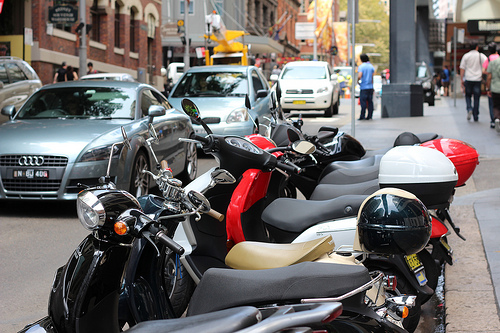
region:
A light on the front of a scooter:
[77, 191, 106, 227]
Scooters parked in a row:
[20, 122, 467, 329]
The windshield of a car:
[24, 83, 135, 123]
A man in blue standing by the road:
[352, 52, 376, 117]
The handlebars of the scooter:
[102, 175, 186, 256]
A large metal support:
[377, 39, 426, 113]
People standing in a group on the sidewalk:
[50, 59, 103, 86]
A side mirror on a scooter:
[295, 140, 315, 155]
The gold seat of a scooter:
[232, 232, 329, 268]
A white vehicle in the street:
[274, 57, 344, 114]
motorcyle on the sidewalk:
[55, 203, 372, 323]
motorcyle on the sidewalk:
[146, 185, 406, 257]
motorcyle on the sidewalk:
[205, 173, 412, 238]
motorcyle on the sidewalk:
[193, 161, 420, 214]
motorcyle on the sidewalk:
[238, 159, 443, 194]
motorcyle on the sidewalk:
[242, 120, 476, 185]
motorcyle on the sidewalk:
[83, 282, 365, 320]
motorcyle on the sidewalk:
[174, 225, 398, 290]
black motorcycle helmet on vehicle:
[351, 181, 433, 256]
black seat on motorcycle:
[188, 249, 360, 300]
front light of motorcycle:
[77, 186, 99, 221]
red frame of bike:
[238, 163, 265, 241]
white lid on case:
[395, 142, 453, 179]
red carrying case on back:
[438, 129, 469, 160]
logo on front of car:
[14, 143, 52, 165]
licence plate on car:
[14, 163, 58, 184]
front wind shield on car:
[2, 75, 130, 129]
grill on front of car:
[0, 156, 57, 174]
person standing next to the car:
[346, 42, 384, 122]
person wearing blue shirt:
[351, 62, 381, 98]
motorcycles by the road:
[124, 104, 418, 331]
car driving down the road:
[14, 70, 174, 210]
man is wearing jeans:
[351, 84, 393, 124]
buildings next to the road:
[14, 5, 210, 90]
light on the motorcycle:
[64, 199, 136, 241]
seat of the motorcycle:
[228, 231, 336, 281]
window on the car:
[39, 77, 144, 138]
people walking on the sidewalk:
[437, 24, 498, 141]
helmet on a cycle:
[360, 196, 436, 256]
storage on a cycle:
[368, 140, 464, 186]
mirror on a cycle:
[210, 158, 240, 203]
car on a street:
[0, 88, 130, 179]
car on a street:
[188, 56, 273, 109]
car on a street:
[278, 51, 335, 96]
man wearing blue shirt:
[352, 50, 378, 117]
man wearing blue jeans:
[355, 40, 376, 120]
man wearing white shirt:
[453, 31, 488, 121]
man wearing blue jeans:
[451, 29, 482, 115]